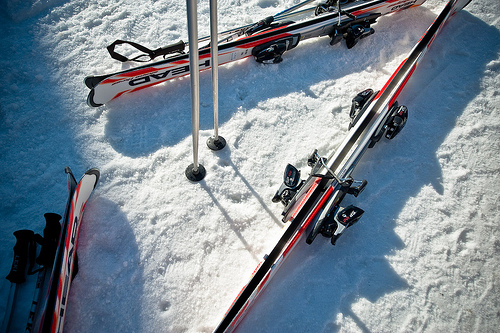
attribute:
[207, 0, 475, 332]
skating board — red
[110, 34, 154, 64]
band — black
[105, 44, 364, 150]
shadow — cast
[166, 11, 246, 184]
poles — silver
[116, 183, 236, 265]
snow — hard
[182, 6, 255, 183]
pole — skinny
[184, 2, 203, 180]
ski pole — standing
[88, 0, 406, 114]
skis — red, black, white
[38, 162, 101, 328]
skis — red, black, white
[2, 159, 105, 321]
ski — red, white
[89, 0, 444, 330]
skis — white, red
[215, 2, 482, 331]
skis — red, black, white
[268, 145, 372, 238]
ski brackets — black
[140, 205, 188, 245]
ice — white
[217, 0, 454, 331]
ski — red, white, black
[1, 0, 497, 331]
snow — white, powdery, glaring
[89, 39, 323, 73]
skis — lying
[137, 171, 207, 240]
sun — shining